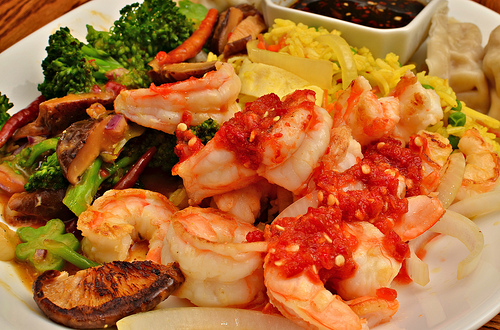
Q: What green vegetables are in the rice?
A: Peas.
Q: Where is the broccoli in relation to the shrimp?
A: To the left.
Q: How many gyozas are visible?
A: 2.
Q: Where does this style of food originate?
A: China.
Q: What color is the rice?
A: Yellow.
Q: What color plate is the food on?
A: White.